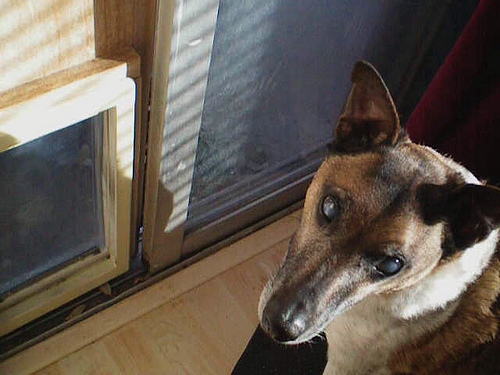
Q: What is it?
A: A dog.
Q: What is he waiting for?
A: Owner.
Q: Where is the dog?
A: On the floor.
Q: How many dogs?
A: 1.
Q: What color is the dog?
A: Brown.